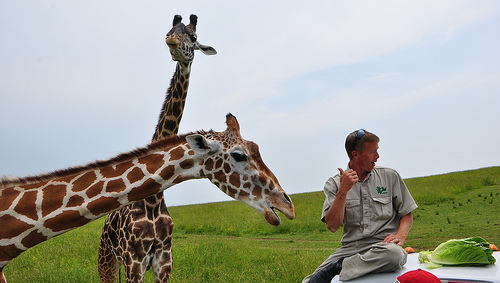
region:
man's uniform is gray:
[315, 123, 413, 276]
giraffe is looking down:
[65, 85, 308, 277]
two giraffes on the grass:
[1, 1, 307, 281]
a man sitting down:
[294, 125, 434, 278]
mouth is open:
[269, 198, 294, 228]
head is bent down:
[0, 113, 306, 282]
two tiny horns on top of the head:
[169, 8, 199, 29]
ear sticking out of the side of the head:
[189, 40, 221, 59]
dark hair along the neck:
[3, 123, 200, 190]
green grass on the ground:
[7, 161, 499, 282]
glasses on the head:
[350, 125, 372, 142]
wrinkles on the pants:
[366, 243, 388, 255]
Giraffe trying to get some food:
[4, 115, 308, 281]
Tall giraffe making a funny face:
[98, 13, 230, 280]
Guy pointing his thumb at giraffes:
[289, 125, 426, 282]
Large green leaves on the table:
[417, 229, 494, 280]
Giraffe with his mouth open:
[195, 120, 308, 245]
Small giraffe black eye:
[219, 136, 261, 169]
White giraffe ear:
[179, 132, 232, 160]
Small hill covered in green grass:
[7, 155, 498, 282]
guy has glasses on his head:
[314, 112, 421, 279]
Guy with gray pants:
[297, 228, 407, 281]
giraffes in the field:
[2, 1, 304, 276]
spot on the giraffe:
[125, 165, 140, 179]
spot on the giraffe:
[87, 184, 103, 196]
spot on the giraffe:
[40, 188, 64, 215]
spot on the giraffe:
[11, 190, 41, 220]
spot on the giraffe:
[173, 101, 182, 119]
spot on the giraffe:
[228, 171, 244, 189]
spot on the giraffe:
[136, 220, 155, 235]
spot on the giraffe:
[0, 213, 27, 235]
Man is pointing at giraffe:
[301, 120, 418, 282]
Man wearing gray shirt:
[296, 130, 419, 282]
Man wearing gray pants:
[300, 128, 417, 281]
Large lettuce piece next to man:
[423, 232, 494, 265]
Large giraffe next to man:
[98, 10, 217, 280]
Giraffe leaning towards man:
[0, 108, 297, 280]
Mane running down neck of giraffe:
[0, 129, 207, 189]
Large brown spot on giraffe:
[124, 164, 146, 184]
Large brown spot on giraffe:
[84, 178, 104, 199]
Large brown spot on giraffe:
[68, 168, 98, 192]